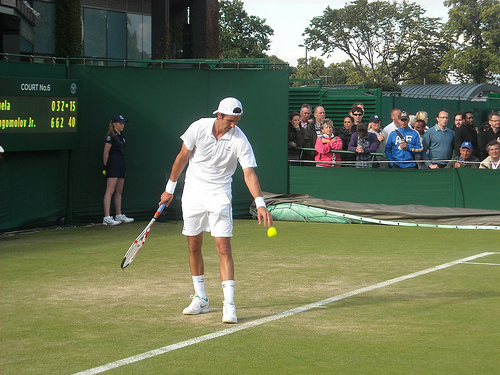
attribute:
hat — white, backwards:
[209, 97, 243, 110]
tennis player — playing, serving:
[156, 94, 274, 324]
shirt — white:
[179, 120, 262, 199]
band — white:
[254, 194, 270, 210]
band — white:
[165, 180, 177, 192]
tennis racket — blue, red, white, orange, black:
[115, 204, 171, 274]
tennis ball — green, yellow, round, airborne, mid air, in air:
[268, 225, 280, 239]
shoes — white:
[184, 295, 238, 323]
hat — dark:
[115, 116, 128, 122]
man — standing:
[391, 114, 424, 168]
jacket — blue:
[382, 129, 423, 165]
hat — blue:
[398, 111, 409, 122]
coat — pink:
[314, 136, 344, 165]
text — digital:
[1, 97, 76, 133]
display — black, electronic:
[2, 77, 79, 154]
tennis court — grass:
[4, 213, 495, 374]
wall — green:
[2, 62, 82, 229]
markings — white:
[56, 248, 500, 375]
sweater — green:
[424, 126, 455, 162]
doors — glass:
[81, 7, 151, 66]